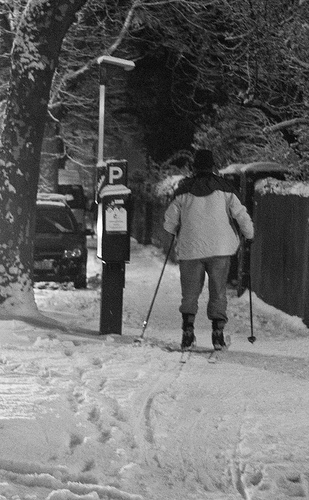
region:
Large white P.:
[108, 165, 122, 183]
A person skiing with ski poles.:
[163, 148, 255, 349]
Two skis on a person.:
[179, 335, 229, 364]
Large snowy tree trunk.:
[0, 1, 84, 320]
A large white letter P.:
[107, 165, 123, 184]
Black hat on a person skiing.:
[192, 149, 216, 167]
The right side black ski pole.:
[246, 238, 257, 345]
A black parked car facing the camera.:
[34, 192, 94, 289]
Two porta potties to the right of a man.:
[218, 159, 285, 296]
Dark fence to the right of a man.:
[246, 181, 306, 329]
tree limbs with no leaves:
[63, 3, 305, 102]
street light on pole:
[96, 54, 133, 252]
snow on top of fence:
[165, 161, 306, 326]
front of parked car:
[33, 195, 88, 287]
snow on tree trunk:
[1, 81, 49, 315]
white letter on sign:
[107, 159, 126, 185]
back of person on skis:
[137, 148, 255, 344]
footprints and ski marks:
[54, 358, 303, 497]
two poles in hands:
[131, 233, 255, 344]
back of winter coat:
[163, 174, 253, 260]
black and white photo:
[21, 73, 291, 270]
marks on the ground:
[66, 370, 191, 467]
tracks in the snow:
[61, 344, 143, 460]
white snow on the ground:
[135, 368, 213, 422]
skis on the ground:
[180, 315, 240, 372]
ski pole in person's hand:
[224, 241, 275, 353]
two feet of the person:
[167, 299, 238, 349]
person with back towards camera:
[131, 146, 268, 263]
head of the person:
[179, 142, 225, 190]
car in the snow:
[10, 194, 98, 308]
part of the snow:
[265, 446, 274, 454]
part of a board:
[212, 359, 215, 367]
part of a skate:
[212, 332, 215, 339]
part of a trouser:
[220, 311, 221, 314]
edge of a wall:
[112, 307, 121, 318]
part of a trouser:
[222, 296, 226, 303]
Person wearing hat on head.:
[184, 150, 221, 166]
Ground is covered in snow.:
[83, 400, 195, 459]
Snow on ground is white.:
[37, 396, 178, 454]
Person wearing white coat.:
[178, 208, 237, 241]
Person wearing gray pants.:
[175, 260, 242, 302]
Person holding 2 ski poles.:
[136, 245, 271, 355]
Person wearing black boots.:
[171, 319, 241, 347]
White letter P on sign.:
[103, 164, 137, 194]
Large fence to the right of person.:
[250, 186, 301, 295]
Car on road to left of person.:
[33, 202, 88, 304]